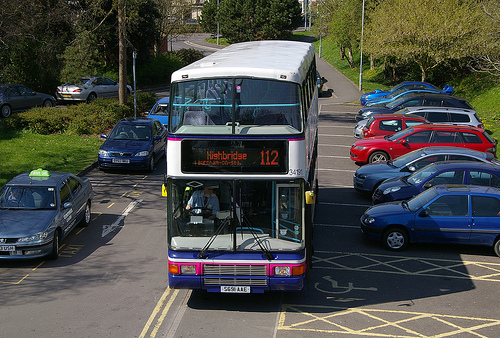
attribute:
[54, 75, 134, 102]
gray car — grey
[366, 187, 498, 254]
car — blue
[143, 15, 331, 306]
bus — red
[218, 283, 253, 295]
plate — white, black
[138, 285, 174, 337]
lines — double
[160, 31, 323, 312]
grey stone — blue, white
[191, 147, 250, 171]
words — electronic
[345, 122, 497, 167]
car — red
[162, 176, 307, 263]
windshield — red, white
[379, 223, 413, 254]
tire — black, round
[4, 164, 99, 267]
taxi — blue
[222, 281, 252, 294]
license plate — white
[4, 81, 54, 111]
car — parked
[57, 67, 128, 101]
car — parked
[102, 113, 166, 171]
car — parked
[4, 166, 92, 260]
car — parked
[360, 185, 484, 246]
car — parked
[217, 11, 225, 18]
leaf — green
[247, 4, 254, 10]
leaf — green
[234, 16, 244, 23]
leaf — green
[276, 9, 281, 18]
leaf — green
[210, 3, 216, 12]
leaf — green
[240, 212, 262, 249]
windshield wiper — black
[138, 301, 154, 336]
line — yellow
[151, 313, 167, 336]
line — yellow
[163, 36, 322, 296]
bus — blue